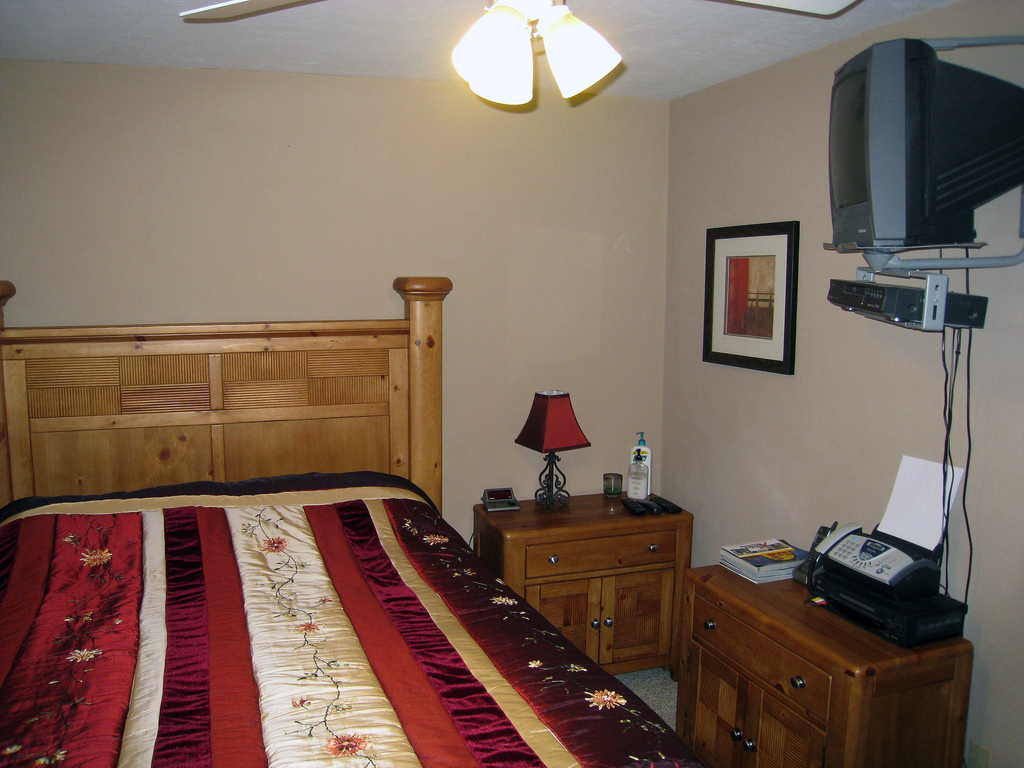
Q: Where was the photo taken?
A: In the bedroom.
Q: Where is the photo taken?
A: In a bedroom.